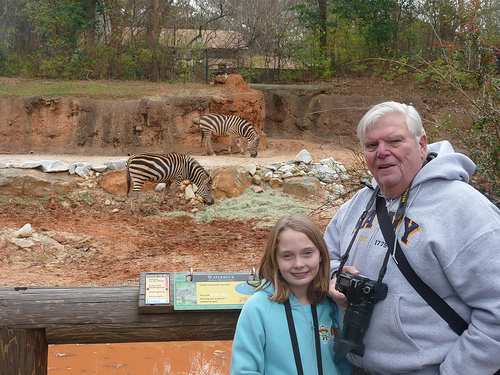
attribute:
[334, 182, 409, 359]
camera — black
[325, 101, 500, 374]
man — heavyset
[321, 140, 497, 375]
sweat shirt — grey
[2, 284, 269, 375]
fence — wooden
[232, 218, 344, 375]
girl — standing, young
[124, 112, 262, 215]
zebras — eating, grazing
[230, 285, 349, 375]
sweatshirt — blue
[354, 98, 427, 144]
hair — grey, white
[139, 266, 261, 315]
sign — informational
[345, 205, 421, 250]
lettering — yellow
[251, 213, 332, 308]
hair — light brown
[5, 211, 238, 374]
water — muddy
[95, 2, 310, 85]
trees — bare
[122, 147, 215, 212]
zebra — black, white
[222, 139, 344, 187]
rocks — white